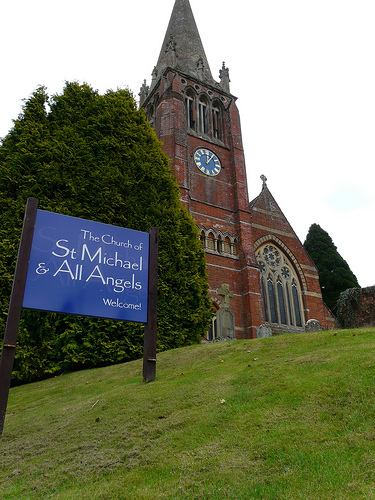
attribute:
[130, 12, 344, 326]
church — blue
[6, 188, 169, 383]
poles — black 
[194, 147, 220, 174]
clock — blue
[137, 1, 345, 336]
building — reddish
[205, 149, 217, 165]
hands — gold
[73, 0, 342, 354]
building — brick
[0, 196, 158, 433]
sign — blue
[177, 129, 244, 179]
clock — blue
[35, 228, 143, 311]
letters — white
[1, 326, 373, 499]
hill — grassy, small